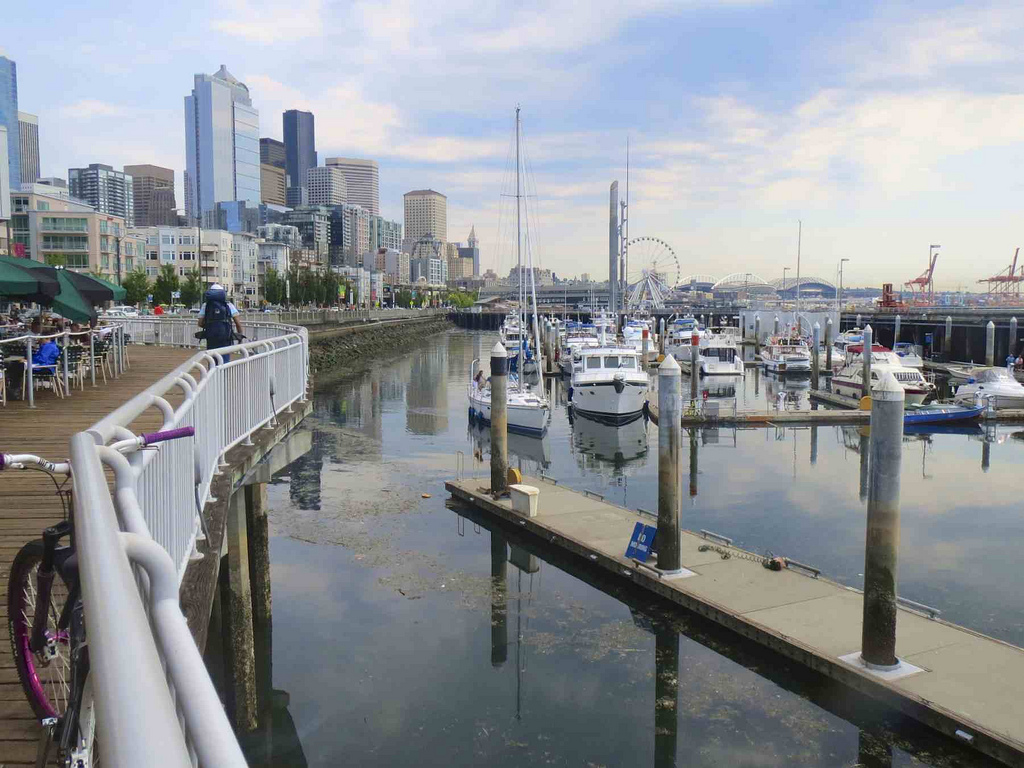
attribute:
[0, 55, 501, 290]
buildings — lots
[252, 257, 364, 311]
trees — series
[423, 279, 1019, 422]
boats — docked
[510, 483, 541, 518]
container — white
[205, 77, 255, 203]
glass — reflective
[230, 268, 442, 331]
street — side of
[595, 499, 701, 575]
sign — blue, white